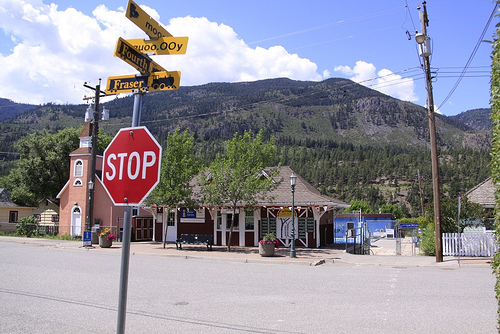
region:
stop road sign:
[75, 121, 185, 211]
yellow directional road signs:
[80, 2, 240, 92]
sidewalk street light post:
[275, 161, 300, 256]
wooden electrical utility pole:
[370, 1, 465, 261]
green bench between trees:
[166, 225, 226, 255]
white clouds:
[25, 10, 86, 85]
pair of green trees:
[152, 120, 252, 260]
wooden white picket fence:
[450, 226, 490, 261]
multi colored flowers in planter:
[85, 221, 121, 256]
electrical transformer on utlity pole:
[80, 103, 114, 125]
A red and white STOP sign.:
[84, 115, 172, 226]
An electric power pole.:
[406, 4, 456, 267]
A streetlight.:
[284, 171, 301, 257]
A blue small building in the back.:
[330, 202, 407, 249]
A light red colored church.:
[51, 98, 163, 248]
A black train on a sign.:
[150, 72, 178, 91]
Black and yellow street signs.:
[97, 0, 217, 107]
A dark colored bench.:
[172, 227, 228, 259]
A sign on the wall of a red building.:
[179, 202, 210, 224]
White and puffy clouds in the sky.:
[1, 1, 440, 112]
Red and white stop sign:
[93, 118, 168, 200]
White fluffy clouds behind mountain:
[23, 1, 422, 118]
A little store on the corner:
[148, 141, 341, 273]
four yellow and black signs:
[76, 14, 200, 107]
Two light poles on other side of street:
[63, 2, 499, 262]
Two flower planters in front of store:
[92, 230, 282, 249]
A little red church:
[38, 98, 166, 248]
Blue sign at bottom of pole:
[76, 222, 101, 254]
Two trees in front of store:
[150, 135, 267, 275]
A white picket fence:
[427, 218, 499, 260]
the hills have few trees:
[173, 81, 425, 138]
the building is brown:
[70, 181, 108, 236]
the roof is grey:
[271, 170, 325, 200]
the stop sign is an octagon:
[101, 134, 170, 220]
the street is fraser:
[85, 75, 194, 90]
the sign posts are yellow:
[106, 8, 188, 91]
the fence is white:
[453, 233, 494, 258]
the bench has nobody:
[171, 231, 221, 260]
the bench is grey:
[181, 230, 213, 249]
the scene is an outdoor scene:
[1, 11, 493, 328]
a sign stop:
[47, 12, 202, 274]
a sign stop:
[66, 121, 236, 322]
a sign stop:
[97, 99, 216, 270]